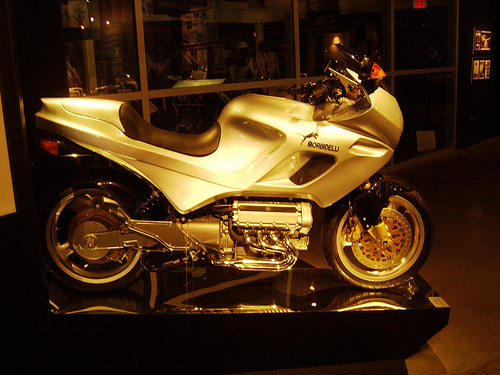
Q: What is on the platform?
A: Motorcycle.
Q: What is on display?
A: Motorcycle.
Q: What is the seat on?
A: Motorcycle.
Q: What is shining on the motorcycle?
A: Light.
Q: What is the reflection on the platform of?
A: Motorcycle.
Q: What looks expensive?
A: The motorcycle.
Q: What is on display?
A: A shiny motorcycle.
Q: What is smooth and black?
A: Motorcycle seat.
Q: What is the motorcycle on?
A: A pedestal.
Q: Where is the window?
A: Behind the motorcycle.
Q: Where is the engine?
A: Under bike.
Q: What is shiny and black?
A: Display platform.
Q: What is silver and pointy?
A: Tail of bike.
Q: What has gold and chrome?
A: Wheel.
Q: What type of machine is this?
A: A motorcycle.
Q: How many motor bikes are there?
A: 1.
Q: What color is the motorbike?
A: White.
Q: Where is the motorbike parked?
A: In a showroom.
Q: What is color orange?
A: The motor bike's lights.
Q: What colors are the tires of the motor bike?
A: Black.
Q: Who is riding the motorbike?
A: No one.